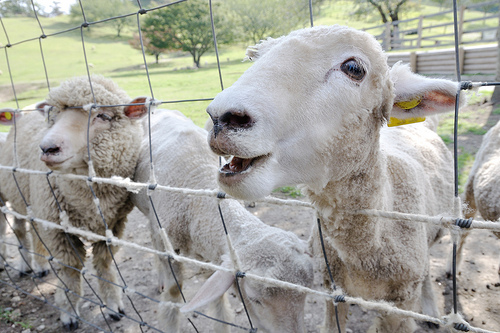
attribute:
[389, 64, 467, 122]
sheep's ear — shaved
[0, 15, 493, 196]
field — grass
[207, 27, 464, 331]
sheep — white, large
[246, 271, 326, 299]
covering — white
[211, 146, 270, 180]
mouth — open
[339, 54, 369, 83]
eyes — large, black, shiny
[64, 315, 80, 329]
feet — black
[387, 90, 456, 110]
inside — pink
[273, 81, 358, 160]
wool — white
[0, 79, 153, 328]
sheep — unshaved, white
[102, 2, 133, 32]
tree — in a distance